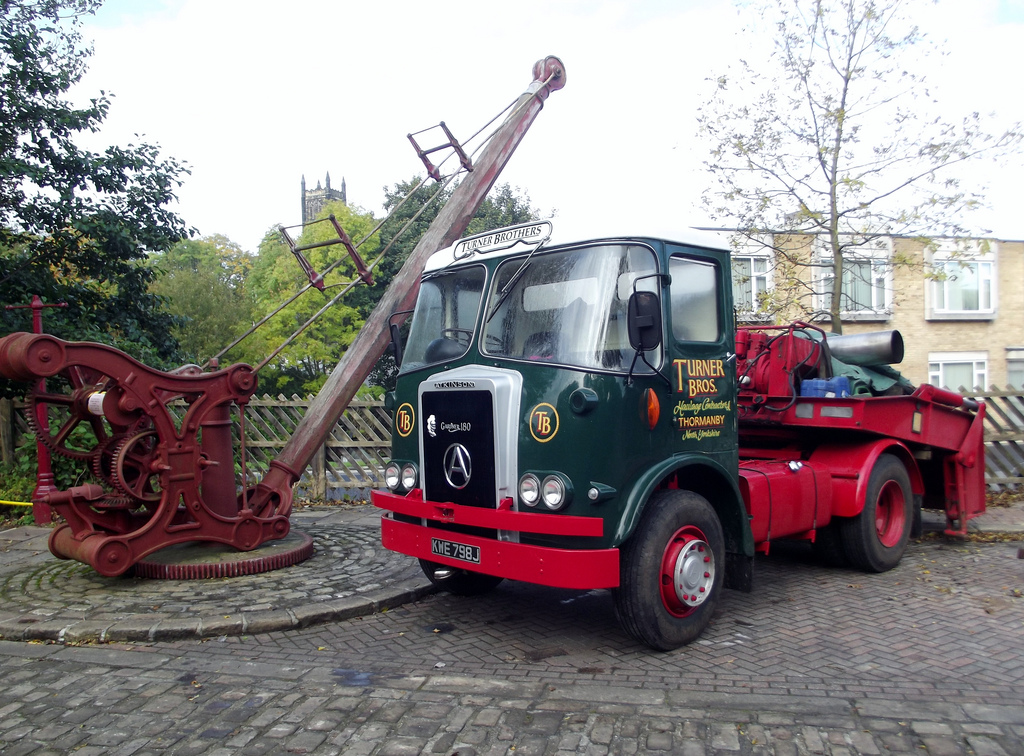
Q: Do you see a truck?
A: Yes, there is a truck.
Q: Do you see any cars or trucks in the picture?
A: Yes, there is a truck.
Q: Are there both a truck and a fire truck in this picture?
A: No, there is a truck but no fire trucks.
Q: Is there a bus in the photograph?
A: No, there are no buses.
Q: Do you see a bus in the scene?
A: No, there are no buses.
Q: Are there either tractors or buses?
A: No, there are no buses or tractors.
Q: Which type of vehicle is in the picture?
A: The vehicle is a truck.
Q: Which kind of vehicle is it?
A: The vehicle is a truck.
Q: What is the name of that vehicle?
A: This is a truck.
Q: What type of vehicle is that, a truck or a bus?
A: This is a truck.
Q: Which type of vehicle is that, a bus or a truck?
A: This is a truck.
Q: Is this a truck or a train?
A: This is a truck.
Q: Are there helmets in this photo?
A: No, there are no helmets.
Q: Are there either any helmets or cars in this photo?
A: No, there are no helmets or cars.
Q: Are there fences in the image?
A: Yes, there is a fence.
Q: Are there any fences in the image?
A: Yes, there is a fence.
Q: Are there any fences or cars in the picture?
A: Yes, there is a fence.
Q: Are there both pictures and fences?
A: No, there is a fence but no pictures.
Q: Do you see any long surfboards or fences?
A: Yes, there is a long fence.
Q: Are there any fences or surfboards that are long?
A: Yes, the fence is long.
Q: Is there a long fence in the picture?
A: Yes, there is a long fence.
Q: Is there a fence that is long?
A: Yes, there is a fence that is long.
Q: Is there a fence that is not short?
A: Yes, there is a long fence.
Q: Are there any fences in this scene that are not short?
A: Yes, there is a long fence.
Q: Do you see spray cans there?
A: No, there are no spray cans.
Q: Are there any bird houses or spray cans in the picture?
A: No, there are no spray cans or bird houses.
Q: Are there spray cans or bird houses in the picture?
A: No, there are no spray cans or bird houses.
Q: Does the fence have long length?
A: Yes, the fence is long.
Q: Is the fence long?
A: Yes, the fence is long.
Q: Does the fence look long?
A: Yes, the fence is long.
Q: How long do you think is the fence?
A: The fence is long.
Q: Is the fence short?
A: No, the fence is long.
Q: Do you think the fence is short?
A: No, the fence is long.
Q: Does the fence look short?
A: No, the fence is long.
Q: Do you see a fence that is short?
A: No, there is a fence but it is long.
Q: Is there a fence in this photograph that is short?
A: No, there is a fence but it is long.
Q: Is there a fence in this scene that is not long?
A: No, there is a fence but it is long.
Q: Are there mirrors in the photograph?
A: Yes, there is a mirror.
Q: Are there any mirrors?
A: Yes, there is a mirror.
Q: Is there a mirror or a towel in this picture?
A: Yes, there is a mirror.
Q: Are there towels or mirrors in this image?
A: Yes, there is a mirror.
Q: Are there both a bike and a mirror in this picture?
A: No, there is a mirror but no bikes.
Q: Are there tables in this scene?
A: No, there are no tables.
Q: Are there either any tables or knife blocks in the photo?
A: No, there are no tables or knife blocks.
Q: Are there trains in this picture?
A: No, there are no trains.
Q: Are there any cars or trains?
A: No, there are no trains or cars.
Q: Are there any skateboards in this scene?
A: No, there are no skateboards.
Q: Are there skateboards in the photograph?
A: No, there are no skateboards.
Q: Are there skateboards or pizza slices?
A: No, there are no skateboards or pizza slices.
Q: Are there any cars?
A: No, there are no cars.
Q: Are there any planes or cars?
A: No, there are no cars or planes.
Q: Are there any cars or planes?
A: No, there are no cars or planes.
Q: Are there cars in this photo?
A: No, there are no cars.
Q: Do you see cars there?
A: No, there are no cars.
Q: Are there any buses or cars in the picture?
A: No, there are no cars or buses.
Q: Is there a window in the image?
A: Yes, there is a window.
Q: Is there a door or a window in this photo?
A: Yes, there is a window.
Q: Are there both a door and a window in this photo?
A: Yes, there are both a window and a door.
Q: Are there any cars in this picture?
A: No, there are no cars.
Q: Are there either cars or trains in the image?
A: No, there are no cars or trains.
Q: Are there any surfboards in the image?
A: No, there are no surfboards.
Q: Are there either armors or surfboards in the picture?
A: No, there are no surfboards or armors.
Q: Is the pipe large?
A: Yes, the pipe is large.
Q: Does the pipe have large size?
A: Yes, the pipe is large.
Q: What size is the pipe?
A: The pipe is large.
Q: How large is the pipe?
A: The pipe is large.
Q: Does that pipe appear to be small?
A: No, the pipe is large.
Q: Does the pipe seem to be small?
A: No, the pipe is large.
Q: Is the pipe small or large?
A: The pipe is large.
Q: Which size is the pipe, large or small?
A: The pipe is large.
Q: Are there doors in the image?
A: Yes, there is a door.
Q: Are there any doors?
A: Yes, there is a door.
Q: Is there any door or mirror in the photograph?
A: Yes, there is a door.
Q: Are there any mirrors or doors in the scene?
A: Yes, there is a door.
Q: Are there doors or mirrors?
A: Yes, there is a door.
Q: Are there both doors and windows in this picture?
A: Yes, there are both a door and a window.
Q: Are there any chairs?
A: No, there are no chairs.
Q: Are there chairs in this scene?
A: No, there are no chairs.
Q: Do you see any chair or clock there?
A: No, there are no chairs or clocks.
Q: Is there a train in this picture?
A: No, there are no trains.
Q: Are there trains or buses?
A: No, there are no trains or buses.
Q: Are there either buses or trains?
A: No, there are no trains or buses.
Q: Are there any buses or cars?
A: No, there are no cars or buses.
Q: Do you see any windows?
A: Yes, there is a window.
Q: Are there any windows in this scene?
A: Yes, there is a window.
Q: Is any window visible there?
A: Yes, there is a window.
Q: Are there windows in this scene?
A: Yes, there is a window.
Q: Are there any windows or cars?
A: Yes, there is a window.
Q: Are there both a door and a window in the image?
A: Yes, there are both a window and a door.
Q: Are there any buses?
A: No, there are no buses.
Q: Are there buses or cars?
A: No, there are no buses or cars.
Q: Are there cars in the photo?
A: No, there are no cars.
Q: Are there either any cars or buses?
A: No, there are no cars or buses.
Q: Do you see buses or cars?
A: No, there are no cars or buses.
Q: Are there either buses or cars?
A: No, there are no cars or buses.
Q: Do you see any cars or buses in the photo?
A: No, there are no cars or buses.